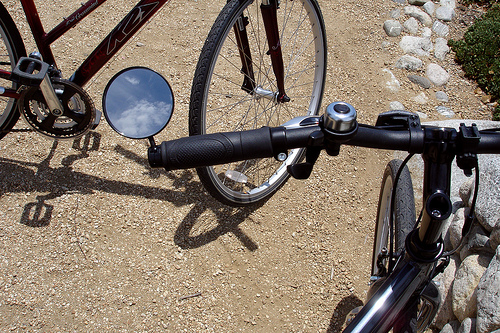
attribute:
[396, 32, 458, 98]
rocks — buried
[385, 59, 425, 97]
rock — small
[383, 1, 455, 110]
stones — gray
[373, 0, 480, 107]
rock — small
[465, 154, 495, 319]
stones — stacked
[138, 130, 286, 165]
handlebar grip — black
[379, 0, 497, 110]
rock — small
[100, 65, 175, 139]
mirror — round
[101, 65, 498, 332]
bike — red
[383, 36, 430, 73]
rock — small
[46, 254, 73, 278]
rock — small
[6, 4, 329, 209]
bike — red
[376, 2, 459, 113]
path — brown